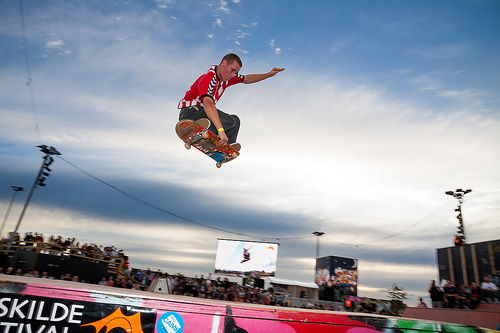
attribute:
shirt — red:
[172, 64, 247, 111]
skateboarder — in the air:
[173, 50, 289, 172]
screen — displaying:
[207, 230, 282, 280]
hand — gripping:
[214, 130, 229, 150]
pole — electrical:
[0, 143, 63, 259]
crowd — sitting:
[412, 271, 497, 311]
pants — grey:
[176, 105, 242, 145]